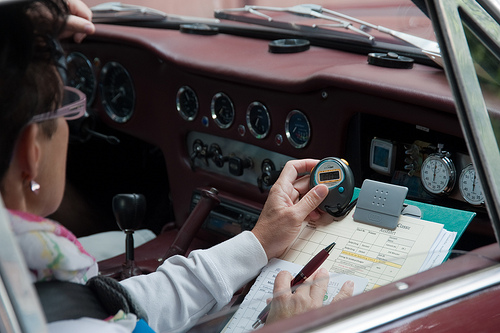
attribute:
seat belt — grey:
[27, 271, 152, 326]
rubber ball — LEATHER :
[108, 191, 146, 233]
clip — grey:
[350, 176, 407, 231]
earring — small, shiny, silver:
[19, 166, 49, 197]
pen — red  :
[252, 244, 335, 325]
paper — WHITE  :
[390, 236, 426, 273]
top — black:
[109, 180, 148, 228]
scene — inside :
[1, 1, 498, 331]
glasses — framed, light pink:
[31, 80, 103, 138]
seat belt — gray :
[31, 272, 151, 322]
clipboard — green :
[212, 154, 484, 331]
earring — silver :
[21, 174, 44, 205]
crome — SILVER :
[426, 40, 498, 94]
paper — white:
[239, 174, 471, 320]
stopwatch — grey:
[305, 155, 358, 217]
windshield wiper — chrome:
[211, 3, 448, 67]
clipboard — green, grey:
[284, 178, 479, 269]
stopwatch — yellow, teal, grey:
[308, 155, 353, 214]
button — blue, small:
[337, 183, 345, 192]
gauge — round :
[247, 104, 272, 138]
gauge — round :
[282, 107, 310, 145]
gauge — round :
[209, 89, 240, 131]